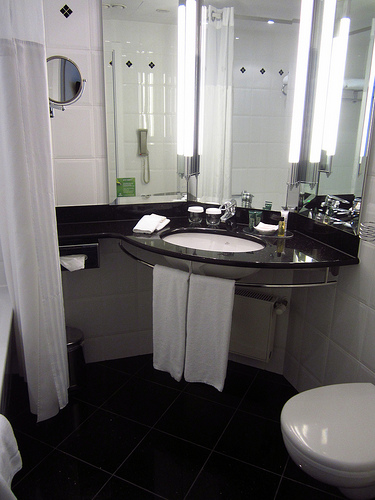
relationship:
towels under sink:
[151, 263, 237, 395] [160, 224, 269, 282]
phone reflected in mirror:
[138, 130, 152, 186] [101, 2, 375, 238]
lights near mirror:
[179, 0, 352, 190] [101, 2, 375, 238]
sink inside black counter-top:
[160, 224, 269, 282] [54, 205, 361, 276]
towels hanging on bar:
[151, 263, 237, 395] [116, 241, 340, 289]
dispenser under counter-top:
[59, 242, 100, 271] [54, 205, 361, 276]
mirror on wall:
[46, 56, 88, 114] [44, 0, 112, 209]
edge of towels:
[230, 278, 237, 320] [151, 263, 237, 395]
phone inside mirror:
[138, 130, 152, 186] [101, 2, 375, 238]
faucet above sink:
[219, 200, 238, 223] [160, 224, 269, 282]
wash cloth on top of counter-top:
[132, 211, 170, 236] [54, 205, 361, 276]